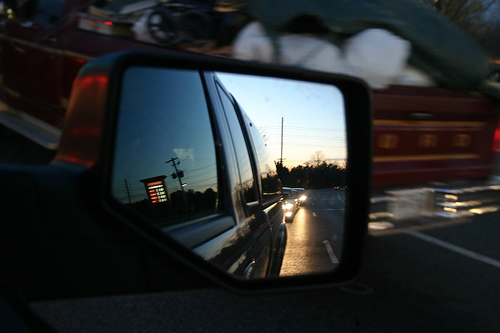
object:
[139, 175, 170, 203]
gas station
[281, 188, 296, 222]
car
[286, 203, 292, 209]
headlights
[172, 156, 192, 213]
electric pole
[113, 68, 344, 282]
mirror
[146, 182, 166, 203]
sign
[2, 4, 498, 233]
truck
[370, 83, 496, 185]
tailgate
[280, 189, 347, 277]
road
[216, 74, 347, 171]
sky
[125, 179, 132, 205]
electric pole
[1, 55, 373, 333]
vehicle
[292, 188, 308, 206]
car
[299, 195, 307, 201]
headlights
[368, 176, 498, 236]
bumper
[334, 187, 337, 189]
red light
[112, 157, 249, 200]
wires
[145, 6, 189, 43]
wheel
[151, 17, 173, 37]
spokes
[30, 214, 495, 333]
road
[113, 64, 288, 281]
car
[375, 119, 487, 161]
license plate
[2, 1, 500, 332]
background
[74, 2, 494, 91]
items